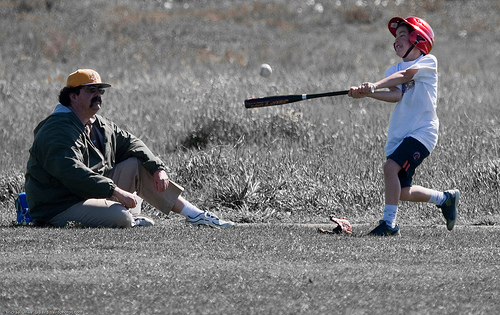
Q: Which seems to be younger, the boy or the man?
A: The boy is younger than the man.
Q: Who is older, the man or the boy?
A: The man is older than the boy.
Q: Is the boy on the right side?
A: Yes, the boy is on the right of the image.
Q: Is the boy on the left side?
A: No, the boy is on the right of the image.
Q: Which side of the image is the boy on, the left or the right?
A: The boy is on the right of the image.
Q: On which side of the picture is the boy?
A: The boy is on the right of the image.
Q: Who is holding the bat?
A: The boy is holding the bat.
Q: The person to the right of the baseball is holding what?
A: The boy is holding the bat.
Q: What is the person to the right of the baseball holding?
A: The boy is holding the bat.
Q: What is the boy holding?
A: The boy is holding the bat.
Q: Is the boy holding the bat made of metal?
A: Yes, the boy is holding the bat.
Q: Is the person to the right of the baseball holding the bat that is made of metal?
A: Yes, the boy is holding the bat.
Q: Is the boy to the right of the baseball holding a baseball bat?
A: No, the boy is holding the bat.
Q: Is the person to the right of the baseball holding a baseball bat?
A: No, the boy is holding the bat.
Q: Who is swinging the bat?
A: The boy is swinging the bat.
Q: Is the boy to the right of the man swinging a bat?
A: Yes, the boy is swinging a bat.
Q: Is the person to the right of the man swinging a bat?
A: Yes, the boy is swinging a bat.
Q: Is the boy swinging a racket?
A: No, the boy is swinging a bat.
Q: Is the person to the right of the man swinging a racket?
A: No, the boy is swinging a bat.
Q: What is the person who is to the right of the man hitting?
A: The boy is hitting the baseball.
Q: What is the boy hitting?
A: The boy is hitting the baseball.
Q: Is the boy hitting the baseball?
A: Yes, the boy is hitting the baseball.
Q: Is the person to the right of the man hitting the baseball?
A: Yes, the boy is hitting the baseball.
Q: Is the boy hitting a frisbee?
A: No, the boy is hitting the baseball.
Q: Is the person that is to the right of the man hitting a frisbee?
A: No, the boy is hitting the baseball.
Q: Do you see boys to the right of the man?
A: Yes, there is a boy to the right of the man.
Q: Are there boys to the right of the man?
A: Yes, there is a boy to the right of the man.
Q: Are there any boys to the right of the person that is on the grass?
A: Yes, there is a boy to the right of the man.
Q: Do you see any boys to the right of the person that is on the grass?
A: Yes, there is a boy to the right of the man.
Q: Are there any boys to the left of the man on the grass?
A: No, the boy is to the right of the man.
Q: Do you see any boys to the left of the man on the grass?
A: No, the boy is to the right of the man.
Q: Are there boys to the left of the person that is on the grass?
A: No, the boy is to the right of the man.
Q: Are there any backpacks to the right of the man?
A: No, there is a boy to the right of the man.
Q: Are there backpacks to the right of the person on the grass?
A: No, there is a boy to the right of the man.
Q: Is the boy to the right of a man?
A: Yes, the boy is to the right of a man.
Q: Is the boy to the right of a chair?
A: No, the boy is to the right of a man.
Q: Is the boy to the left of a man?
A: No, the boy is to the right of a man.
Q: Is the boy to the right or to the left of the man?
A: The boy is to the right of the man.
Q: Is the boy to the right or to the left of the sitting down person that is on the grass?
A: The boy is to the right of the man.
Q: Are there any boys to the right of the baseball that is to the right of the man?
A: Yes, there is a boy to the right of the baseball.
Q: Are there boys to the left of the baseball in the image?
A: No, the boy is to the right of the baseball.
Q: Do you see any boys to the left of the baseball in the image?
A: No, the boy is to the right of the baseball.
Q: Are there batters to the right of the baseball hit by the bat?
A: No, there is a boy to the right of the baseball.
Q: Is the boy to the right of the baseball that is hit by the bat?
A: Yes, the boy is to the right of the baseball.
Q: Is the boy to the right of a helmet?
A: No, the boy is to the right of the baseball.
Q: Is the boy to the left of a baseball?
A: No, the boy is to the right of a baseball.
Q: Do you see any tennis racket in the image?
A: No, there are no rackets.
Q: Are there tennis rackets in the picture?
A: No, there are no tennis rackets.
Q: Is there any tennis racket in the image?
A: No, there are no rackets.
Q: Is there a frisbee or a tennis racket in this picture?
A: No, there are no rackets or frisbees.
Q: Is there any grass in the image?
A: Yes, there is grass.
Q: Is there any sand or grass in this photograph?
A: Yes, there is grass.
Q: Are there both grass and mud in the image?
A: No, there is grass but no mud.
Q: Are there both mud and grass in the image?
A: No, there is grass but no mud.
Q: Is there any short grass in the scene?
A: Yes, there is short grass.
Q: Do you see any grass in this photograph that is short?
A: Yes, there is grass that is short.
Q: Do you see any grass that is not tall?
A: Yes, there is short grass.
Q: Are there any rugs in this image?
A: No, there are no rugs.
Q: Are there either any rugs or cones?
A: No, there are no rugs or cones.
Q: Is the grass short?
A: Yes, the grass is short.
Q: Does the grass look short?
A: Yes, the grass is short.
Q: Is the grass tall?
A: No, the grass is short.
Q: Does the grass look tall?
A: No, the grass is short.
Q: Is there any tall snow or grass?
A: No, there is grass but it is short.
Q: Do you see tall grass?
A: No, there is grass but it is short.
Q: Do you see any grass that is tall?
A: No, there is grass but it is short.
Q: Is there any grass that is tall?
A: No, there is grass but it is short.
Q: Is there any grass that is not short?
A: No, there is grass but it is short.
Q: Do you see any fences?
A: No, there are no fences.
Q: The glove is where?
A: The glove is on the grass.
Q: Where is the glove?
A: The glove is on the grass.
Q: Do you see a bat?
A: Yes, there is a bat.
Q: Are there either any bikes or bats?
A: Yes, there is a bat.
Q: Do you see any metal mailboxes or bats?
A: Yes, there is a metal bat.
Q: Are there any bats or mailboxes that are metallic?
A: Yes, the bat is metallic.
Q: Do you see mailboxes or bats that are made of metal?
A: Yes, the bat is made of metal.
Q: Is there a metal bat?
A: Yes, there is a bat that is made of metal.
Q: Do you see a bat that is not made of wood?
A: Yes, there is a bat that is made of metal.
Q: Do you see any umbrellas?
A: No, there are no umbrellas.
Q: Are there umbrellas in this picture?
A: No, there are no umbrellas.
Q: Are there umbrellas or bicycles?
A: No, there are no umbrellas or bicycles.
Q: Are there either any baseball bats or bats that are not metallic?
A: No, there is a bat but it is metallic.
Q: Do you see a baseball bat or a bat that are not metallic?
A: No, there is a bat but it is metallic.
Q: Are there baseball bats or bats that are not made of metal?
A: No, there is a bat but it is made of metal.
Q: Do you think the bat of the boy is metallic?
A: Yes, the bat is metallic.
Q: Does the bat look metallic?
A: Yes, the bat is metallic.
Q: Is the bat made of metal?
A: Yes, the bat is made of metal.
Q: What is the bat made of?
A: The bat is made of metal.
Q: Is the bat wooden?
A: No, the bat is metallic.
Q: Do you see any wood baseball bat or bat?
A: No, there is a bat but it is metallic.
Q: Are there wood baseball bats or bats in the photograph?
A: No, there is a bat but it is metallic.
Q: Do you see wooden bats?
A: No, there is a bat but it is metallic.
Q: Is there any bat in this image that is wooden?
A: No, there is a bat but it is metallic.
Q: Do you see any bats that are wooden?
A: No, there is a bat but it is metallic.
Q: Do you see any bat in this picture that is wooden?
A: No, there is a bat but it is metallic.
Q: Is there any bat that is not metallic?
A: No, there is a bat but it is metallic.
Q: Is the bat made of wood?
A: No, the bat is made of metal.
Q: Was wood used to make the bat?
A: No, the bat is made of metal.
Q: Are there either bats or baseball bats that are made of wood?
A: No, there is a bat but it is made of metal.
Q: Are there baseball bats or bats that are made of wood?
A: No, there is a bat but it is made of metal.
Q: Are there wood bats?
A: No, there is a bat but it is made of metal.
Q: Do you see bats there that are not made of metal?
A: No, there is a bat but it is made of metal.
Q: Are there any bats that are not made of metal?
A: No, there is a bat but it is made of metal.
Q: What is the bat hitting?
A: The bat is hitting the baseball.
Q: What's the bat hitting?
A: The bat is hitting the baseball.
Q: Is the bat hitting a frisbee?
A: No, the bat is hitting the baseball.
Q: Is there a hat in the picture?
A: Yes, there is a hat.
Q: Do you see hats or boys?
A: Yes, there is a hat.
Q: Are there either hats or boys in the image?
A: Yes, there is a hat.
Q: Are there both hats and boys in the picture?
A: Yes, there are both a hat and a boy.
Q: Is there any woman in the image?
A: No, there are no women.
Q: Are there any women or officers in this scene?
A: No, there are no women or officers.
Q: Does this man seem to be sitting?
A: Yes, the man is sitting.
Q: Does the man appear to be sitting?
A: Yes, the man is sitting.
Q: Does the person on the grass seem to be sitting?
A: Yes, the man is sitting.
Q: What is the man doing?
A: The man is sitting.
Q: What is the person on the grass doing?
A: The man is sitting.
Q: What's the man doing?
A: The man is sitting.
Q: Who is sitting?
A: The man is sitting.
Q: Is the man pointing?
A: No, the man is sitting.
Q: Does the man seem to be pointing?
A: No, the man is sitting.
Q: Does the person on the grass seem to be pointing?
A: No, the man is sitting.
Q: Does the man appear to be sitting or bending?
A: The man is sitting.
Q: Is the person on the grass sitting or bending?
A: The man is sitting.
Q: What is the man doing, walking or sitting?
A: The man is sitting.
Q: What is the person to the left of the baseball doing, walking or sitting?
A: The man is sitting.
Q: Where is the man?
A: The man is on the grass.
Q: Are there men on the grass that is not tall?
A: Yes, there is a man on the grass.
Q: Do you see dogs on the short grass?
A: No, there is a man on the grass.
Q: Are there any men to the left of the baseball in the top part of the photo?
A: Yes, there is a man to the left of the baseball.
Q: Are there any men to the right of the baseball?
A: No, the man is to the left of the baseball.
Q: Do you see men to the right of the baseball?
A: No, the man is to the left of the baseball.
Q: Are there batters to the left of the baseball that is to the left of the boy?
A: No, there is a man to the left of the baseball.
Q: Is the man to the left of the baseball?
A: Yes, the man is to the left of the baseball.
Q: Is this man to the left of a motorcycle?
A: No, the man is to the left of the baseball.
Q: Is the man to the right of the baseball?
A: No, the man is to the left of the baseball.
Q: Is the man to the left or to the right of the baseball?
A: The man is to the left of the baseball.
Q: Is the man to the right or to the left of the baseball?
A: The man is to the left of the baseball.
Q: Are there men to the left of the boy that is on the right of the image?
A: Yes, there is a man to the left of the boy.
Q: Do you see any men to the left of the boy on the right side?
A: Yes, there is a man to the left of the boy.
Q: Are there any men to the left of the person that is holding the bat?
A: Yes, there is a man to the left of the boy.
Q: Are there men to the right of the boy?
A: No, the man is to the left of the boy.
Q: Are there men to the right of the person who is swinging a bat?
A: No, the man is to the left of the boy.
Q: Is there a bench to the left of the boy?
A: No, there is a man to the left of the boy.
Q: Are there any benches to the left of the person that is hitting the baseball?
A: No, there is a man to the left of the boy.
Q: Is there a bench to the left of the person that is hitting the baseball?
A: No, there is a man to the left of the boy.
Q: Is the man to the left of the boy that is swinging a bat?
A: Yes, the man is to the left of the boy.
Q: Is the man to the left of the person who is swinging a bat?
A: Yes, the man is to the left of the boy.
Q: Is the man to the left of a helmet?
A: No, the man is to the left of the boy.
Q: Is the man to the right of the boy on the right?
A: No, the man is to the left of the boy.